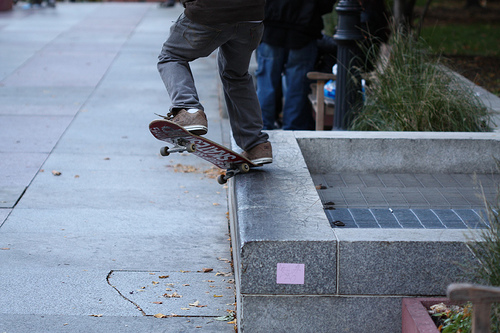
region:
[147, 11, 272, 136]
man wearing brown pants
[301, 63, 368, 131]
a beach can be seen behind a pole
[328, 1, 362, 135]
a pole next to a bench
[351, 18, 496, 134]
a plant next to a pole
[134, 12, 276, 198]
a person skating on the street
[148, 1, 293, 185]
a skater is on a border of a small wall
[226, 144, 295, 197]
front skater touch the border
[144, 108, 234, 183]
part of the skater that is in the air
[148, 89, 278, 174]
person wears brown shoes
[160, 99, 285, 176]
shoes has white soles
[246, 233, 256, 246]
edge of a wall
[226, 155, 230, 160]
part of a board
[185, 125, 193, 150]
part of a wheel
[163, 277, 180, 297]
part of a surface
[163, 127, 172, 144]
tip of a board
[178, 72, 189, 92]
part of a jeans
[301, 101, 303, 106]
leg of a man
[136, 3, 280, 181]
legs of a skater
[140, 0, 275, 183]
skateboard is on an edge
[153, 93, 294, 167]
shoes are color brown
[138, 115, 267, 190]
skateboard is small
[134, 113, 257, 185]
skateboard has white letters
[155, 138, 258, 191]
wheels of skateboard is black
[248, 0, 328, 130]
somebody wearing blue jeans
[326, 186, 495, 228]
vents on side of a street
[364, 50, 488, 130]
a bush on back of people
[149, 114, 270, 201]
skateboard is red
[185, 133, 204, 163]
skateboard wheels are yellow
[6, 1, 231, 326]
sidewalk is grey and cracked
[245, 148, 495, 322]
stone bench is grey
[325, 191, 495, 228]
bricks behind bench are blue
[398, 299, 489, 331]
red planter near bench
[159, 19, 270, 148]
person wears grey shorts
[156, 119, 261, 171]
person on red skateboard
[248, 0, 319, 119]
person wears blue jeans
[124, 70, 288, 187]
person on skateboard in photo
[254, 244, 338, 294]
pink sticker on concrete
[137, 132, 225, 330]
leaves on sidewalk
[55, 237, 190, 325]
square shaped crack in concrete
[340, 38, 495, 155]
green grass in corner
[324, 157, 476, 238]
blue tiles inside concrete barrier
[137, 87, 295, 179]
man waring brown shoes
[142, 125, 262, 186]
white lettering on bottom of skateboard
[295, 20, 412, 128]
brown bench in photo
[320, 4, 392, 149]
black metal pole in photo